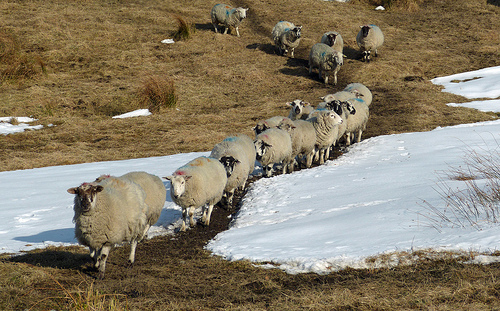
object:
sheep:
[162, 156, 228, 234]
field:
[7, 45, 192, 154]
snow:
[472, 75, 499, 94]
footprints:
[381, 135, 413, 165]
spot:
[188, 157, 211, 167]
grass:
[0, 0, 86, 98]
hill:
[373, 177, 469, 256]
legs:
[324, 68, 330, 85]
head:
[286, 99, 311, 114]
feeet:
[150, 35, 275, 64]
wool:
[321, 52, 326, 58]